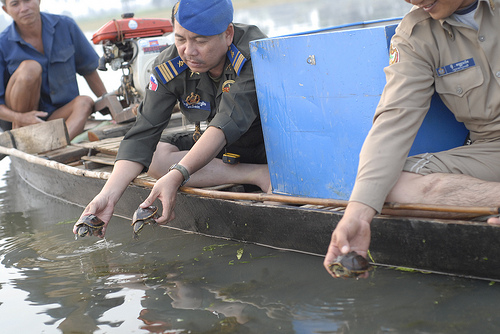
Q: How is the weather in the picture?
A: It is clear.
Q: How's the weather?
A: It is clear.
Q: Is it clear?
A: Yes, it is clear.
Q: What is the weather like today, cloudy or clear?
A: It is clear.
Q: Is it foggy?
A: No, it is clear.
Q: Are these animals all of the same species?
A: Yes, all the animals are turtles.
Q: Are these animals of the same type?
A: Yes, all the animals are turtles.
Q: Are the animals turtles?
A: Yes, all the animals are turtles.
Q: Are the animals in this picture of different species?
A: No, all the animals are turtles.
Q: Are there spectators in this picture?
A: No, there are no spectators.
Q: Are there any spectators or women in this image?
A: No, there are no spectators or women.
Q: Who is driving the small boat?
A: The man is driving the boat.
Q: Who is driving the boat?
A: The man is driving the boat.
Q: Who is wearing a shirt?
A: The man is wearing a shirt.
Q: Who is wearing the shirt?
A: The man is wearing a shirt.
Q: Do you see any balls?
A: No, there are no balls.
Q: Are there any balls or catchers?
A: No, there are no balls or catchers.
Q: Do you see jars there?
A: No, there are no jars.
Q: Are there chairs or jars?
A: No, there are no jars or chairs.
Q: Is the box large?
A: Yes, the box is large.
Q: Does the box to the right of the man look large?
A: Yes, the box is large.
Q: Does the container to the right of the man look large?
A: Yes, the box is large.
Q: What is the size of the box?
A: The box is large.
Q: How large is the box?
A: The box is large.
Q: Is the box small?
A: No, the box is large.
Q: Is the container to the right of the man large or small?
A: The box is large.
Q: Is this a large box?
A: Yes, this is a large box.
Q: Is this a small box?
A: No, this is a large box.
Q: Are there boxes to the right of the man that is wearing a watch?
A: Yes, there is a box to the right of the man.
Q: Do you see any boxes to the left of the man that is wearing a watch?
A: No, the box is to the right of the man.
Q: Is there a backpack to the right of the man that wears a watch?
A: No, there is a box to the right of the man.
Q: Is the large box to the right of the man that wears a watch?
A: Yes, the box is to the right of the man.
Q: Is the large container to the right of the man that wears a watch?
A: Yes, the box is to the right of the man.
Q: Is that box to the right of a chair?
A: No, the box is to the right of the man.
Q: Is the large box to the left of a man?
A: No, the box is to the right of a man.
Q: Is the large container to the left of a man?
A: No, the box is to the right of a man.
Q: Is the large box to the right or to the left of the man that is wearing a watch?
A: The box is to the right of the man.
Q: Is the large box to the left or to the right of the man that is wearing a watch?
A: The box is to the right of the man.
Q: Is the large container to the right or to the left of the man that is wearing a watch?
A: The box is to the right of the man.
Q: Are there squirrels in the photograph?
A: No, there are no squirrels.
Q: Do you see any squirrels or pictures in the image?
A: No, there are no squirrels or pictures.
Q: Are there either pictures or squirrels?
A: No, there are no squirrels or pictures.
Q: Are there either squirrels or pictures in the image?
A: No, there are no squirrels or pictures.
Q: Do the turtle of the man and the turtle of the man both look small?
A: Yes, both the turtle and the turtle are small.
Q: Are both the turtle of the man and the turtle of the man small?
A: Yes, both the turtle and the turtle are small.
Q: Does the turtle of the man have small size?
A: Yes, the turtle is small.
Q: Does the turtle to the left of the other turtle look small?
A: Yes, the turtle is small.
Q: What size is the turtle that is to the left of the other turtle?
A: The turtle is small.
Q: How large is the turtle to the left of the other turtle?
A: The turtle is small.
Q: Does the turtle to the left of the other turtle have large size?
A: No, the turtle is small.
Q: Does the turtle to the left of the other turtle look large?
A: No, the turtle is small.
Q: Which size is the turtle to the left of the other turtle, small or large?
A: The turtle is small.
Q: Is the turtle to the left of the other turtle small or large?
A: The turtle is small.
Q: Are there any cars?
A: No, there are no cars.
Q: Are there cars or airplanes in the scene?
A: No, there are no cars or airplanes.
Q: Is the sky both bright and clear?
A: Yes, the sky is bright and clear.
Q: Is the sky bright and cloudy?
A: No, the sky is bright but clear.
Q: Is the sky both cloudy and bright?
A: No, the sky is bright but clear.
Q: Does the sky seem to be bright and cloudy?
A: No, the sky is bright but clear.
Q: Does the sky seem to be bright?
A: Yes, the sky is bright.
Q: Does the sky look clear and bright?
A: Yes, the sky is clear and bright.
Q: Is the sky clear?
A: Yes, the sky is clear.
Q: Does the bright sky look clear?
A: Yes, the sky is clear.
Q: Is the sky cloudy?
A: No, the sky is clear.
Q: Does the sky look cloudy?
A: No, the sky is clear.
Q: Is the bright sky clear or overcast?
A: The sky is clear.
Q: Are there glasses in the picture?
A: No, there are no glasses.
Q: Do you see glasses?
A: No, there are no glasses.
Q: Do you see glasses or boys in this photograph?
A: No, there are no glasses or boys.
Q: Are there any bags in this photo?
A: No, there are no bags.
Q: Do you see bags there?
A: No, there are no bags.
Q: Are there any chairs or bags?
A: No, there are no bags or chairs.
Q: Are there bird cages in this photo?
A: No, there are no bird cages.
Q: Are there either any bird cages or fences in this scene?
A: No, there are no bird cages or fences.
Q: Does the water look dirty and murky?
A: Yes, the water is dirty and murky.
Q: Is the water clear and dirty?
A: No, the water is dirty but murky.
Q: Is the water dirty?
A: Yes, the water is dirty.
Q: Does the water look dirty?
A: Yes, the water is dirty.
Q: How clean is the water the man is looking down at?
A: The water is dirty.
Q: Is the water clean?
A: No, the water is dirty.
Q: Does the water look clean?
A: No, the water is dirty.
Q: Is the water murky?
A: Yes, the water is murky.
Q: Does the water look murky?
A: Yes, the water is murky.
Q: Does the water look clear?
A: No, the water is murky.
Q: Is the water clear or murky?
A: The water is murky.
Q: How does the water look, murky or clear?
A: The water is murky.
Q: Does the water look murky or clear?
A: The water is murky.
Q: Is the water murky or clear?
A: The water is murky.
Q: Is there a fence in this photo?
A: No, there are no fences.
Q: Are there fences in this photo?
A: No, there are no fences.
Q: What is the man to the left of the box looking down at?
A: The man is looking down at the water.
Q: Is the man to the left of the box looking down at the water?
A: Yes, the man is looking down at the water.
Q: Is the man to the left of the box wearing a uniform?
A: Yes, the man is wearing a uniform.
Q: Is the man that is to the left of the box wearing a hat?
A: No, the man is wearing a uniform.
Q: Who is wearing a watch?
A: The man is wearing a watch.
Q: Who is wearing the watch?
A: The man is wearing a watch.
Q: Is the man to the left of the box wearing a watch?
A: Yes, the man is wearing a watch.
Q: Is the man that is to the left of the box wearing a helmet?
A: No, the man is wearing a watch.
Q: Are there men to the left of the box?
A: Yes, there is a man to the left of the box.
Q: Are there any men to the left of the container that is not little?
A: Yes, there is a man to the left of the box.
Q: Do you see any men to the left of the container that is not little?
A: Yes, there is a man to the left of the box.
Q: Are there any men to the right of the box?
A: No, the man is to the left of the box.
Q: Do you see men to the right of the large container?
A: No, the man is to the left of the box.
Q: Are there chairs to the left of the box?
A: No, there is a man to the left of the box.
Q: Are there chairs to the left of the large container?
A: No, there is a man to the left of the box.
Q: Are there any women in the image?
A: No, there are no women.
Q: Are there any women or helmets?
A: No, there are no women or helmets.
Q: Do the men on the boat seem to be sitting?
A: Yes, the men are sitting.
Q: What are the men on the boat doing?
A: The men are sitting.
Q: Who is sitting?
A: The men are sitting.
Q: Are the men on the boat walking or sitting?
A: The men are sitting.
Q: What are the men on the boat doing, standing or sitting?
A: The men are sitting.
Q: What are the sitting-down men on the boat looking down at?
A: The men are looking down at the water.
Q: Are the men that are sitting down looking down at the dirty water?
A: Yes, the men are looking down at the water.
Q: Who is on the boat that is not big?
A: The men are on the boat.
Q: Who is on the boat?
A: The men are on the boat.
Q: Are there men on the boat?
A: Yes, there are men on the boat.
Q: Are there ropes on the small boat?
A: No, there are men on the boat.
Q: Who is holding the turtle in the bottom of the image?
A: The men are holding the turtle.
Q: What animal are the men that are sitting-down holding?
A: The men are holding the turtle.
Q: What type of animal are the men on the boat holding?
A: The men are holding the turtle.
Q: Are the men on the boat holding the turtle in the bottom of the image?
A: Yes, the men are holding the turtle.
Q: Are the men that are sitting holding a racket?
A: No, the men are holding the turtle.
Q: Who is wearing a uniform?
A: The men are wearing a uniform.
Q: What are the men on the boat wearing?
A: The men are wearing a uniform.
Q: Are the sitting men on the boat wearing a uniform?
A: Yes, the men are wearing a uniform.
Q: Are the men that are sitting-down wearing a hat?
A: No, the men are wearing a uniform.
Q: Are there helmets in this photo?
A: No, there are no helmets.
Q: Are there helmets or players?
A: No, there are no helmets or players.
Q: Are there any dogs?
A: No, there are no dogs.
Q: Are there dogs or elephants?
A: No, there are no dogs or elephants.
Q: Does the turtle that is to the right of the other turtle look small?
A: Yes, the turtle is small.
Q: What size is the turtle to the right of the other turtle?
A: The turtle is small.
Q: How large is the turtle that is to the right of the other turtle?
A: The turtle is small.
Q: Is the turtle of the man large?
A: No, the turtle is small.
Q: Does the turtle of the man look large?
A: No, the turtle is small.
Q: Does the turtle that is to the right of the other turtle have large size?
A: No, the turtle is small.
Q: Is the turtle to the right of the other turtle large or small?
A: The turtle is small.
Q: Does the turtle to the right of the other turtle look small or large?
A: The turtle is small.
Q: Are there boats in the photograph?
A: Yes, there is a boat.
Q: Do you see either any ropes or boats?
A: Yes, there is a boat.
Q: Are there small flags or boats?
A: Yes, there is a small boat.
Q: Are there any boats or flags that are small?
A: Yes, the boat is small.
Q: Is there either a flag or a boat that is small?
A: Yes, the boat is small.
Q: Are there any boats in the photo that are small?
A: Yes, there is a small boat.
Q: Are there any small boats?
A: Yes, there is a small boat.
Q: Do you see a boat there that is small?
A: Yes, there is a boat that is small.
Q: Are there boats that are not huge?
A: Yes, there is a small boat.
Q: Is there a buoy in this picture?
A: No, there are no buoys.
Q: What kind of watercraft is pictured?
A: The watercraft is a boat.